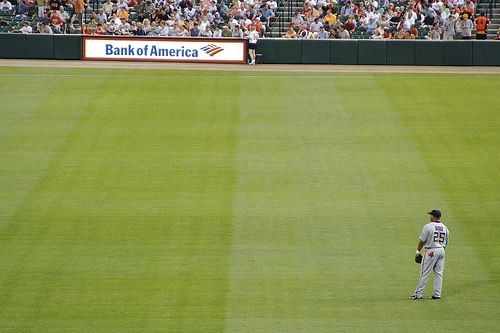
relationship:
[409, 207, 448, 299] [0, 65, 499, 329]
baaseball player on baseball field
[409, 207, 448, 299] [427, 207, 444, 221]
baaseball player wearing hat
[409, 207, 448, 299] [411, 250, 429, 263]
baaseball player wearing catchers mit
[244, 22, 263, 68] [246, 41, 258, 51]
person wearing shorts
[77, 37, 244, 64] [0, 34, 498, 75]
advertisement on fence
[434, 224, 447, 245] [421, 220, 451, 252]
writting on jersey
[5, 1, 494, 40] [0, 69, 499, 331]
crowd are watching game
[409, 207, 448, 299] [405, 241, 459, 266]
baaseball player wearing glove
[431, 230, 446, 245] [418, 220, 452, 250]
number on jersey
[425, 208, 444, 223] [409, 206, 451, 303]
head of baseball player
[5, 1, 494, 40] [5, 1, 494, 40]
crowd of crowd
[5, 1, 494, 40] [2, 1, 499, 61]
crowd in stadium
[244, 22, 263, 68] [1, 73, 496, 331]
person in baseball field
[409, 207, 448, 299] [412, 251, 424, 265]
baaseball player wearing glove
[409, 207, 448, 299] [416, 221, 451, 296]
baaseball player in grey uniform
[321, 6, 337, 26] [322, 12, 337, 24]
person in yellow shirt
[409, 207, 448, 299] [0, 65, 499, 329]
baaseball player standing baseball field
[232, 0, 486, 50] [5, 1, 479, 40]
crowd sitting in stands